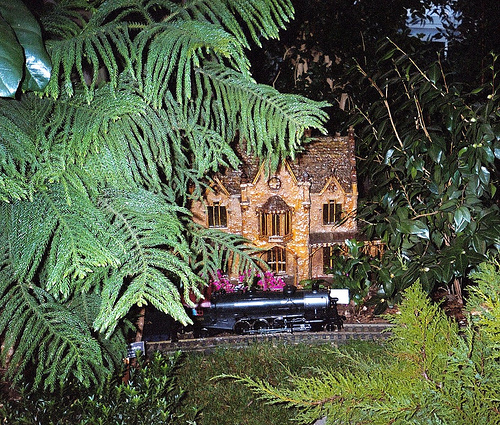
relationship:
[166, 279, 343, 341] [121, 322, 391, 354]
train has tracks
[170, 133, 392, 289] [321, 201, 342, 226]
house has window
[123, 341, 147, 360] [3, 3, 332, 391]
sign on side of tree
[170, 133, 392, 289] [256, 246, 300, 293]
house has archway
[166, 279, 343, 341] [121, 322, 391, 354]
train sitting on tracks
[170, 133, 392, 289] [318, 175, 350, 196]
house has gable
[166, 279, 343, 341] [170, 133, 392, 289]
train passes house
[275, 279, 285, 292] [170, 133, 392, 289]
flower in front of house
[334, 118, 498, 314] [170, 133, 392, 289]
plant beside house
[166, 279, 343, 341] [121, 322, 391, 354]
train rides tracks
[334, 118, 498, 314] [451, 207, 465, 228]
plant has leaf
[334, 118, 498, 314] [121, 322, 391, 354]
plant behind tracks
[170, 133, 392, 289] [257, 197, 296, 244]
house has window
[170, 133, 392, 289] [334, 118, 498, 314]
house behind plant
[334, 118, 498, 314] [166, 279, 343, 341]
plant near train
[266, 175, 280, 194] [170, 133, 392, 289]
clock on side of house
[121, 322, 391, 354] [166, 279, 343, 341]
tracks are under train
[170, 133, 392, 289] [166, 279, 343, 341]
house beside train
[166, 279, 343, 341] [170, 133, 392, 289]
train beside house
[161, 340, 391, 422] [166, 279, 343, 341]
grass beside train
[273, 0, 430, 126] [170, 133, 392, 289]
tree behind house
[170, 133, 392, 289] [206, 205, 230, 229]
house has window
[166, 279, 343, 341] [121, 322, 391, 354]
train on top of tracks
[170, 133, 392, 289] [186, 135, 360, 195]
house has roof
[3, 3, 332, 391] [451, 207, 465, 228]
tree has leaf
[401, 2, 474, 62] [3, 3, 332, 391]
sky behind tree